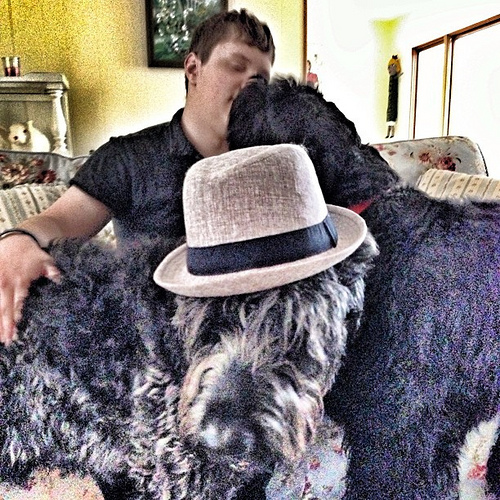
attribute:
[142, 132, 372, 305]
hat — grey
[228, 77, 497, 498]
dog — black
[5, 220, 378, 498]
dog — grey, black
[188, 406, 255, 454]
nose — grey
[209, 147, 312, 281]
hat — brown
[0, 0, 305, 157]
wall — yellow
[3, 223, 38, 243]
braclet — black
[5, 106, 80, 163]
rabbit — white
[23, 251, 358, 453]
dog — grey, white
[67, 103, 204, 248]
shirt — black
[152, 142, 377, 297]
hat — tan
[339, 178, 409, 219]
collar — red